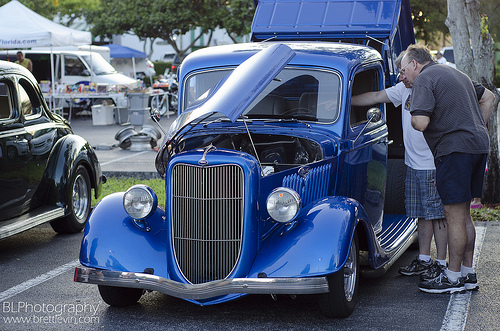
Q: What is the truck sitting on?
A: Pavement.